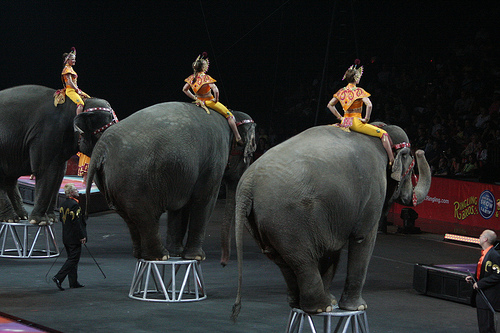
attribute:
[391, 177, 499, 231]
banner — red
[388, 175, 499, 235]
banner — red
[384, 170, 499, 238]
banner — red